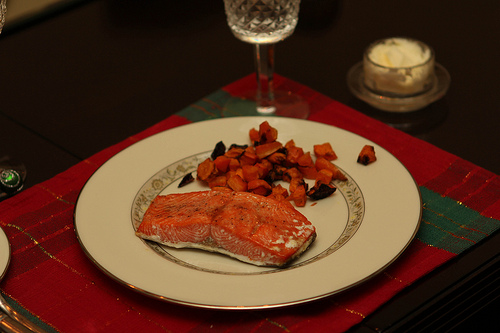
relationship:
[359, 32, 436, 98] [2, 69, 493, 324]
butter dish by placemat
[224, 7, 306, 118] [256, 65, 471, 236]
glass on placemat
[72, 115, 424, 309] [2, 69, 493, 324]
plate on placemat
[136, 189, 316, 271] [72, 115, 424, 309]
salmon on plate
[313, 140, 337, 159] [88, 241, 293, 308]
orange vegetable on plate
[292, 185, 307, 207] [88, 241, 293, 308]
orange vegetable on plate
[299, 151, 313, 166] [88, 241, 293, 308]
orange vegetable on plate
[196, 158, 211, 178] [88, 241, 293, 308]
orange vegetable on plate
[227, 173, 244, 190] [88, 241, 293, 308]
orange vegetable on plate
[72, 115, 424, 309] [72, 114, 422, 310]
plate has rim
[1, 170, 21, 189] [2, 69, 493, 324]
mark on placemat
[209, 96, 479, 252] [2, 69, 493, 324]
green stripe on placemat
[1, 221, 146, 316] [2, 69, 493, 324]
stripe on placemat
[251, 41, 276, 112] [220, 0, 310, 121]
stem on glass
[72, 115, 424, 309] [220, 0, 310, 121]
plate in front of glass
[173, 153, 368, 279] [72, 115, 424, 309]
flowers around plate